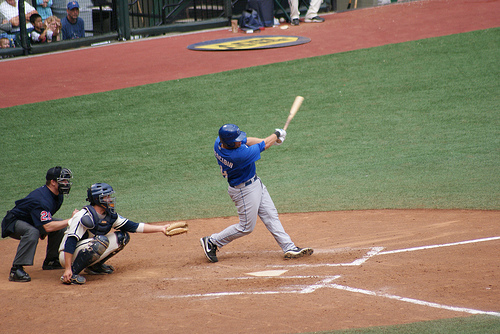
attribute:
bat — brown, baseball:
[275, 93, 303, 143]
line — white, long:
[163, 275, 338, 280]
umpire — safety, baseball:
[0, 160, 75, 285]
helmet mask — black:
[47, 160, 77, 197]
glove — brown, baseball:
[157, 216, 198, 241]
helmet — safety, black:
[85, 177, 126, 212]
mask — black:
[81, 176, 123, 217]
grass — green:
[336, 83, 458, 193]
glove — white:
[268, 118, 310, 153]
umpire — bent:
[6, 165, 72, 280]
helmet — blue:
[217, 124, 248, 146]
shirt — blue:
[212, 136, 269, 186]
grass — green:
[1, 26, 498, 228]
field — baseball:
[19, 32, 483, 330]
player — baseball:
[196, 109, 316, 272]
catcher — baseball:
[64, 183, 164, 284]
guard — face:
[55, 165, 72, 195]